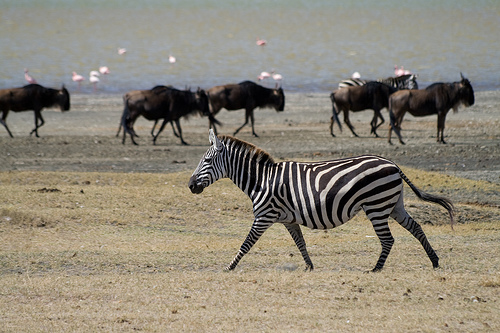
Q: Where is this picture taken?
A: Field.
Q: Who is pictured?
A: No one.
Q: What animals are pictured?
A: Zebra, flamingo, buffalo.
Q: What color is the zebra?
A: Black and white.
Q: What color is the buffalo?
A: Brown.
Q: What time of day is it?
A: Day time.